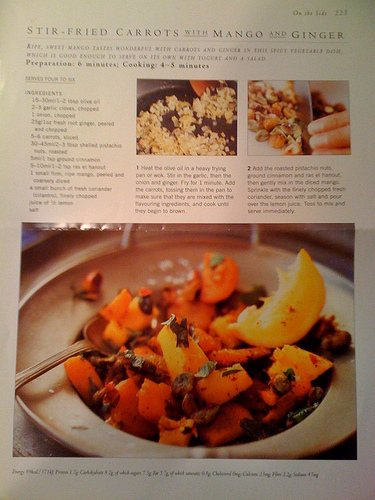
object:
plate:
[16, 231, 354, 458]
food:
[156, 318, 211, 382]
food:
[63, 354, 103, 401]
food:
[156, 417, 192, 444]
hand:
[307, 106, 349, 154]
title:
[35, 15, 368, 45]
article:
[16, 11, 370, 227]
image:
[244, 75, 351, 157]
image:
[134, 78, 237, 157]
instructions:
[23, 22, 351, 218]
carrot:
[200, 257, 239, 303]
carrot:
[193, 364, 252, 405]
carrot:
[99, 287, 151, 332]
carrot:
[56, 360, 105, 399]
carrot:
[136, 377, 166, 424]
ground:
[289, 134, 303, 153]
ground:
[220, 130, 238, 157]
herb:
[193, 357, 215, 380]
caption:
[6, 466, 328, 482]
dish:
[24, 24, 348, 45]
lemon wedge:
[231, 246, 326, 349]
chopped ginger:
[136, 79, 236, 156]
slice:
[228, 246, 324, 346]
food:
[136, 378, 173, 428]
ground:
[244, 43, 280, 70]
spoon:
[13, 312, 114, 397]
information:
[12, 466, 321, 479]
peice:
[153, 318, 208, 384]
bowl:
[16, 238, 355, 457]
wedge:
[226, 245, 324, 350]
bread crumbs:
[135, 79, 237, 155]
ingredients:
[62, 248, 353, 445]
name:
[26, 25, 345, 39]